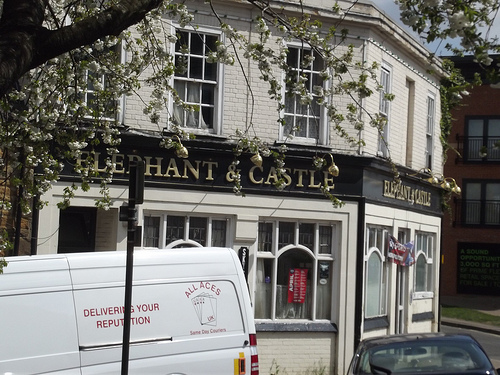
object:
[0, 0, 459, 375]
building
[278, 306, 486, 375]
corner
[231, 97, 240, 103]
brick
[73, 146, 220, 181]
elephant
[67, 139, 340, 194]
sign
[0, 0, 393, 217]
tree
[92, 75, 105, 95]
blossoms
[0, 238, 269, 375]
van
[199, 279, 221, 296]
aces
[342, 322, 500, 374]
car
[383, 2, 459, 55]
daytime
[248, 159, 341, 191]
castle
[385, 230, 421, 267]
flag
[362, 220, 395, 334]
window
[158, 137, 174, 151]
flowers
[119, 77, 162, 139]
branches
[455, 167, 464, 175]
brick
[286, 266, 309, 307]
dates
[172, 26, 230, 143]
windows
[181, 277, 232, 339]
logo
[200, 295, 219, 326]
cards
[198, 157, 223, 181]
lettering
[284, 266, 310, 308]
sign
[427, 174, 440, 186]
lights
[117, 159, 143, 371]
pole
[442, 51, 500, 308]
building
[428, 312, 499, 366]
street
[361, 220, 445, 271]
banner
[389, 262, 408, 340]
doorway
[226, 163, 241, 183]
ampersand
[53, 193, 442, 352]
shop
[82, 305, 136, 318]
delivery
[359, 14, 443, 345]
front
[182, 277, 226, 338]
design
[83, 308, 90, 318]
d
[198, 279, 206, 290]
letters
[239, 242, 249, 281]
name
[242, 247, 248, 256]
letters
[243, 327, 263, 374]
light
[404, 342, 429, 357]
mirror